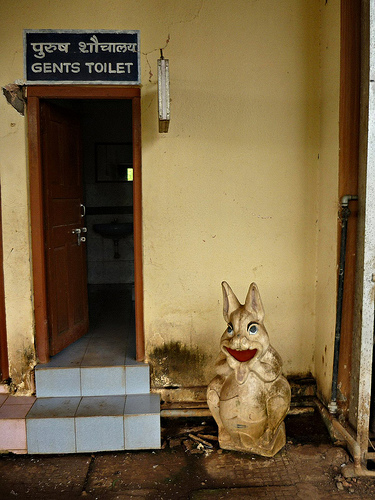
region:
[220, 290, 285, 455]
The dirt rabbit by the steps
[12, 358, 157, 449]
the stairs leading to the door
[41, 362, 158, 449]
the blue steps by the door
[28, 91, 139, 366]
the open door way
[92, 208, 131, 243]
sink in the bathroom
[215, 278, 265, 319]
the rabbits ears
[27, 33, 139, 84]
the sign that says gents toilet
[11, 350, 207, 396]
the dirt on the wall by the steps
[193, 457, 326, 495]
the tile floor in front of the rabbit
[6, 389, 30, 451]
the pink tiles next to the blue tiles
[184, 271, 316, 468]
An odd looking rabbit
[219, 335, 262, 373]
The rabbit is holding his mouth with his hands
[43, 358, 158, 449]
Blue ceramic tiles on a step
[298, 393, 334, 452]
Mud in the corner behind the rabbit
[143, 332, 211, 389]
Mold on the wall from water damage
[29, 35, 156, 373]
This is a public restroom for men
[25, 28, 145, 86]
A public restroom somewhere in the Middle East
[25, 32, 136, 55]
This is written in Arabic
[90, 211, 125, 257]
The sink in the men's restroom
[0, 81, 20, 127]
The wall is crumbling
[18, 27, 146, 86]
a black sign with white letters and white trim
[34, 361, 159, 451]
two blue brick steps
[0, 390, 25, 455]
a pink brick step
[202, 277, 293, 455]
a rabbit statue sitting the corner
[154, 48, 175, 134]
a light hanging on the wall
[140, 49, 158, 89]
a crack in the wall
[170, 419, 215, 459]
trash on the floor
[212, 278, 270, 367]
a head of a rabbit figurine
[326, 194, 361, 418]
a water pipe on the wall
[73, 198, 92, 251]
a door handle and a lock on a door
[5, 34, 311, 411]
This photo is taken by a house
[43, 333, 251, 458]
this looks like a porch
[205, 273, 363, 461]
this is a statue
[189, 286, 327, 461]
this statue is a rabbit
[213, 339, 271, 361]
the rabbits mouth is red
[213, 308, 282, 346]
the rabbits eyes are green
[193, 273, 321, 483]
the rabbit is white and brown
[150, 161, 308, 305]
the wall is off white and brown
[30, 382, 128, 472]
the steps are blue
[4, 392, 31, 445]
this step is pink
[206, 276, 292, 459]
grinning ceramic bunny statue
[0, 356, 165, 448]
steps covered in blue and pink tiles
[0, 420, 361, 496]
rock slab floor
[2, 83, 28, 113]
hole in the wall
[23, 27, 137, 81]
dual language men's toilet sign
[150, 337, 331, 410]
wall section discolored by mildew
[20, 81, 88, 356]
wooden bathroom door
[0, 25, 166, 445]
entryway to men's bathroom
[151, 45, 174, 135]
small cylindrical light fixture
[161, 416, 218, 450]
garbage on paving stones